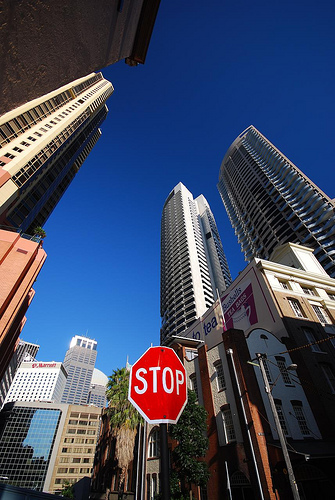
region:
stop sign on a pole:
[123, 336, 199, 498]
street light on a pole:
[248, 354, 310, 499]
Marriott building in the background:
[28, 359, 62, 370]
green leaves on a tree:
[177, 401, 206, 483]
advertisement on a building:
[194, 271, 272, 338]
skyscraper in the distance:
[147, 176, 238, 329]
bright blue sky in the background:
[74, 174, 153, 333]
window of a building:
[287, 397, 319, 436]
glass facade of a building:
[0, 402, 65, 496]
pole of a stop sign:
[151, 425, 176, 498]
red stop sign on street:
[113, 336, 213, 433]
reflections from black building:
[5, 415, 59, 458]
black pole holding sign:
[153, 429, 185, 496]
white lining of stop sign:
[129, 402, 167, 429]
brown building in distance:
[56, 402, 101, 492]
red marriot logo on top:
[25, 348, 66, 381]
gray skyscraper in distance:
[47, 321, 120, 408]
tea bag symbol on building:
[210, 290, 262, 328]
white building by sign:
[15, 363, 68, 416]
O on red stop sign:
[154, 357, 175, 401]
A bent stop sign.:
[124, 335, 191, 425]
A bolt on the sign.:
[159, 347, 165, 353]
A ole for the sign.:
[157, 420, 170, 498]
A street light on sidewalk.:
[252, 350, 310, 499]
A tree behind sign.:
[172, 386, 210, 498]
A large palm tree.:
[100, 364, 135, 498]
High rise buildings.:
[3, 287, 108, 499]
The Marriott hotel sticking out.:
[4, 361, 70, 405]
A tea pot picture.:
[225, 299, 257, 332]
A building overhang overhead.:
[131, 0, 159, 68]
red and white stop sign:
[108, 316, 214, 428]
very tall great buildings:
[130, 88, 319, 486]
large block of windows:
[1, 391, 73, 498]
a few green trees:
[71, 345, 223, 494]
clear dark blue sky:
[129, 10, 314, 211]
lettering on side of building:
[143, 276, 272, 398]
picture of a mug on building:
[215, 289, 268, 333]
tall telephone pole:
[230, 331, 319, 495]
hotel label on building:
[24, 349, 85, 401]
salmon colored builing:
[2, 217, 59, 370]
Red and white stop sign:
[123, 340, 207, 423]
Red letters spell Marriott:
[27, 359, 58, 373]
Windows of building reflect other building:
[2, 395, 54, 499]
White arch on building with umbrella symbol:
[245, 319, 323, 445]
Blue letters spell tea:
[201, 314, 220, 335]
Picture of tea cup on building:
[222, 295, 255, 339]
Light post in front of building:
[241, 346, 317, 497]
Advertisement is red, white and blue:
[169, 292, 283, 333]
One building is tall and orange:
[0, 234, 44, 380]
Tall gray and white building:
[146, 171, 235, 354]